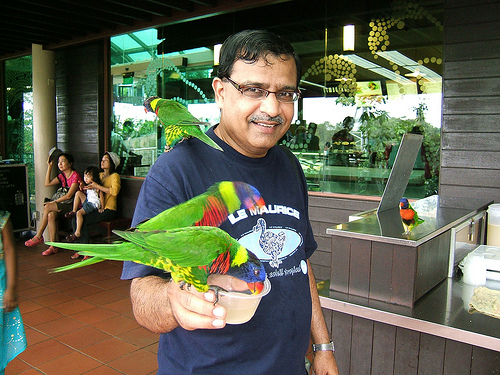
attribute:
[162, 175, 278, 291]
birds — colorful, stadning, drinking, multicolored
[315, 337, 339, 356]
watch — silver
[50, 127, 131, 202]
family — sitting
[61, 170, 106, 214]
child — sitting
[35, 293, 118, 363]
floor — tile, brown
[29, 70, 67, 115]
pole — thick, white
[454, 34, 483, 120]
siding — brown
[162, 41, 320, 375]
man — covered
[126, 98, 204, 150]
bird — green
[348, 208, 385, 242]
counter — black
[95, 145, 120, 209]
woman — sitting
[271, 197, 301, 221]
lettering — white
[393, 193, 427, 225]
bird — standing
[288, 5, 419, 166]
window — large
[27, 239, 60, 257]
sandals — pink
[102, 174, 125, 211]
shirt — yellow